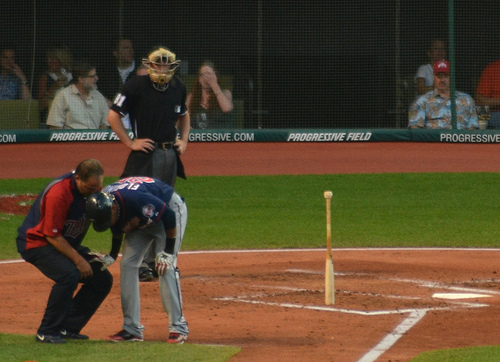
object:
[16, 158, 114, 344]
man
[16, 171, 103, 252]
shirt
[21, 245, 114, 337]
pants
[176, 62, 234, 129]
lady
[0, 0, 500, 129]
net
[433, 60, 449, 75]
red cap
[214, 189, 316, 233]
grass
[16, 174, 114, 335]
uniform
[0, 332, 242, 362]
grass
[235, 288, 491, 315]
diamond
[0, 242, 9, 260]
grass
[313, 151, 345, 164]
ground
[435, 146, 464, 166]
ground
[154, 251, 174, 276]
glove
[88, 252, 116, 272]
glove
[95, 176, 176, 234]
shirt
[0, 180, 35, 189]
grass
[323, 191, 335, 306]
bat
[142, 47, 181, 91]
helmet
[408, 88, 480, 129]
shirt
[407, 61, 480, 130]
fan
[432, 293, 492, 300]
homeplate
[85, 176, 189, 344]
baseball player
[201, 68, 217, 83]
hand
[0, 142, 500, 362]
field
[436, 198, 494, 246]
grass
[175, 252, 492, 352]
dirt